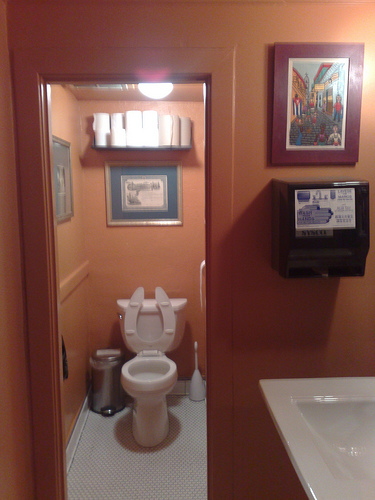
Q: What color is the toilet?
A: White.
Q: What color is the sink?
A: White.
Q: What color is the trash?
A: Silver.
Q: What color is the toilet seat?
A: White.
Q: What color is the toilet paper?
A: White.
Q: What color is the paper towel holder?
A: Black.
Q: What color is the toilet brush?
A: White.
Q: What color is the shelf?
A: Black.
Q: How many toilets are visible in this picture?
A: One.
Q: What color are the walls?
A: Red-brown.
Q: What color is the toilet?
A: White.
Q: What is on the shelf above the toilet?
A: Lots of toilet paper.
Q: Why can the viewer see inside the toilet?
A: Toilet seat is up.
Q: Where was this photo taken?
A: Inside a bathroom.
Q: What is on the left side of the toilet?
A: A metal garbage bin.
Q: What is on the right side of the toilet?
A: A toilet brush.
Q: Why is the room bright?
A: The lights are on.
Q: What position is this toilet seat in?
A: Up.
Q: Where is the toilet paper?
A: On the shelf above the toilet bowl.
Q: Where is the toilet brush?
A: At the right side of the toilet.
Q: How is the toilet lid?
A: Up.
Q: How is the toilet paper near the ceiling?
A: On a shelf.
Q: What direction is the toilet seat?
A: Up.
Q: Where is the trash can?
A: Next to the toilet.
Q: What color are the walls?
A: Orange.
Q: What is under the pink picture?
A: Paper towel dispenser.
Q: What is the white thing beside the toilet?
A: Toilet brush.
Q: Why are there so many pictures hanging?
A: Decoration.